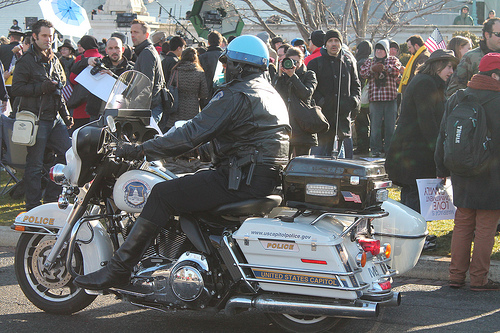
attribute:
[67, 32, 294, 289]
cop — Riding 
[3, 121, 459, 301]
motorcycle — white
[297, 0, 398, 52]
tree — bare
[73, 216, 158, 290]
boot — black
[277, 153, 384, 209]
compartment — black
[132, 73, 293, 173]
jacket — leather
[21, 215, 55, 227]
word — police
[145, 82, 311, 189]
jacket — blue, leather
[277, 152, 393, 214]
box — black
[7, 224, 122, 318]
tire — metal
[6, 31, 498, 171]
people — gathered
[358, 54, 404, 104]
coat — plaid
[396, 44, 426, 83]
scarf — yellow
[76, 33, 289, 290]
officer — Police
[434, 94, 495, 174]
backpack — black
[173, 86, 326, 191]
coat — black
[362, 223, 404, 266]
tail lights — red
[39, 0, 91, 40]
umbrella — blue, white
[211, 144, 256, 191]
pistol — holstered, black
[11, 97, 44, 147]
shoulder bag — brown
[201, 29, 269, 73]
helmet — white, black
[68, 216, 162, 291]
boot — black, leather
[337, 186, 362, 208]
flag — American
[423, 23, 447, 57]
flag — American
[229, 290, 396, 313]
exhaust pipe — silver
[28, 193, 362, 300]
bike — white